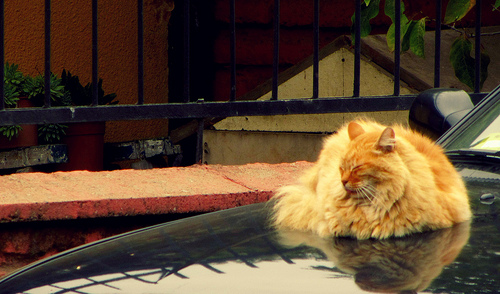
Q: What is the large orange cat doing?
A: Sleeping.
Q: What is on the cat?
A: Tan and orange fur.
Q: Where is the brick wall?
A: Next to the cat.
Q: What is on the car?
A: Reflection of the sky.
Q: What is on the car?
A: Orange furry cat.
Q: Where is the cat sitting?
A: On the car.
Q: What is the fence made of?
A: Iron.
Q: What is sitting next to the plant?
A: A pot.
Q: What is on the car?
A: A cat.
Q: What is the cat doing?
A: It's sleeping.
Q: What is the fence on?
A: A concrete wall.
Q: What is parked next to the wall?
A: A car.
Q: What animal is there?
A: Cat.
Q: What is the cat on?
A: Car.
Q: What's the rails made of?
A: Metal.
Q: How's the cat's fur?
A: Fluffy.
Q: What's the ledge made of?
A: Brick.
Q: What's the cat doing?
A: Sleeping.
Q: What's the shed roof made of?
A: Stucco.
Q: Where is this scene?
A: Driveway.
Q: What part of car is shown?
A: Hood.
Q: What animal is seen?
A: Cat.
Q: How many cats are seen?
A: 1.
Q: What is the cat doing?
A: Sitting in the car.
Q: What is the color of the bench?
A: Red.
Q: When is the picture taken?
A: Daytime.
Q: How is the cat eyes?
A: Closed.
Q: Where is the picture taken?
A: On a car.